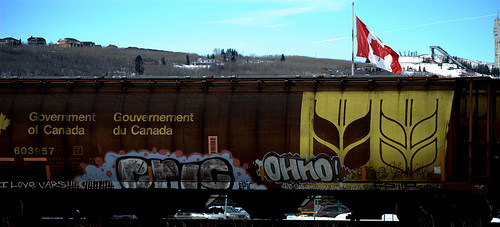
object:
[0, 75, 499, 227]
train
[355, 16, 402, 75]
flag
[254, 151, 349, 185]
graffiti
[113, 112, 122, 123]
letter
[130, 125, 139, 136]
letter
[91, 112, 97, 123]
letter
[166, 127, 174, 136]
letter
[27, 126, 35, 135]
letter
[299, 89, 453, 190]
picture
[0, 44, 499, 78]
mountain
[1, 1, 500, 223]
background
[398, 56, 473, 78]
snow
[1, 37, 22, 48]
building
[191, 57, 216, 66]
building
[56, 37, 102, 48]
building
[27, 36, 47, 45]
building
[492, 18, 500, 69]
building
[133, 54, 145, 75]
tree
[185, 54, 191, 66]
tree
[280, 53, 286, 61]
tree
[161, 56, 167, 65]
tree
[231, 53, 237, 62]
tree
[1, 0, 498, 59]
sky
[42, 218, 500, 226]
tracks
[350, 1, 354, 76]
pole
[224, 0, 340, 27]
cloud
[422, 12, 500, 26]
cloud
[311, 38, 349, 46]
cloud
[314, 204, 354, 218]
car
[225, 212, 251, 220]
car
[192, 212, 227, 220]
car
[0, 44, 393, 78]
field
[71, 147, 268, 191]
graffiti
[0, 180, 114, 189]
graffiti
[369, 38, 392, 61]
leaf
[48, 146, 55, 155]
number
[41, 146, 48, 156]
number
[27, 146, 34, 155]
number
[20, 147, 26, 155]
number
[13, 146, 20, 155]
number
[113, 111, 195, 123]
word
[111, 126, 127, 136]
word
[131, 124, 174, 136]
word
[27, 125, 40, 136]
word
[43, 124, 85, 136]
word